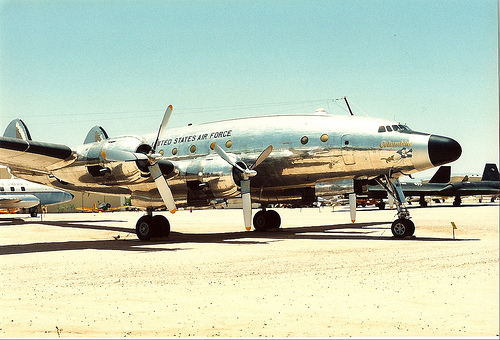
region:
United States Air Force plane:
[0, 78, 471, 236]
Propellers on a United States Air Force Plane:
[93, 101, 200, 216]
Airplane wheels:
[127, 211, 181, 244]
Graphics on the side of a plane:
[372, 133, 421, 170]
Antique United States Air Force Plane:
[0, 74, 477, 256]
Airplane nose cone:
[402, 120, 474, 183]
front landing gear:
[376, 183, 428, 246]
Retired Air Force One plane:
[0, 178, 84, 222]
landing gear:
[127, 206, 302, 238]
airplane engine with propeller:
[45, 123, 190, 213]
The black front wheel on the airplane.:
[385, 212, 418, 241]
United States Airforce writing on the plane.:
[150, 127, 237, 148]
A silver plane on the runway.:
[2, 102, 480, 242]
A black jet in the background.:
[375, 162, 498, 204]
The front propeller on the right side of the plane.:
[210, 142, 278, 217]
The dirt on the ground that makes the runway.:
[1, 241, 498, 338]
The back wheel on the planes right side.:
[127, 207, 171, 244]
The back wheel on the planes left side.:
[255, 207, 290, 237]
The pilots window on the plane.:
[378, 123, 415, 134]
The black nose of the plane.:
[427, 132, 469, 168]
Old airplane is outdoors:
[6, 71, 474, 257]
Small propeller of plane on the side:
[202, 128, 282, 238]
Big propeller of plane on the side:
[69, 95, 191, 240]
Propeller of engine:
[58, 94, 185, 229]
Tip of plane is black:
[420, 124, 469, 181]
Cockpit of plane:
[361, 104, 433, 187]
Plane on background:
[1, 161, 75, 232]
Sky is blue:
[5, 6, 495, 113]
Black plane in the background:
[403, 158, 498, 213]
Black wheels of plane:
[117, 199, 427, 249]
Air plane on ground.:
[9, 98, 481, 240]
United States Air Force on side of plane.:
[150, 131, 239, 148]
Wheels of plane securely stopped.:
[132, 206, 424, 243]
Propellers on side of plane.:
[96, 108, 293, 228]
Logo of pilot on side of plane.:
[375, 135, 422, 167]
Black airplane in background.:
[368, 163, 498, 212]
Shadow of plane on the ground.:
[1, 210, 478, 266]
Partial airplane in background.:
[0, 161, 79, 228]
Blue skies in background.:
[0, 3, 488, 185]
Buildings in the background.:
[2, 163, 329, 222]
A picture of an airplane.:
[0, 38, 463, 284]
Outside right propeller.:
[84, 116, 194, 220]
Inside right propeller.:
[202, 138, 284, 235]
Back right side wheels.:
[131, 205, 190, 257]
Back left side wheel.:
[244, 200, 295, 238]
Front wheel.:
[375, 202, 422, 248]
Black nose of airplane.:
[418, 127, 473, 168]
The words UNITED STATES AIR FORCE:
[149, 124, 246, 147]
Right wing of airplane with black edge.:
[4, 130, 86, 179]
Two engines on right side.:
[74, 131, 283, 216]